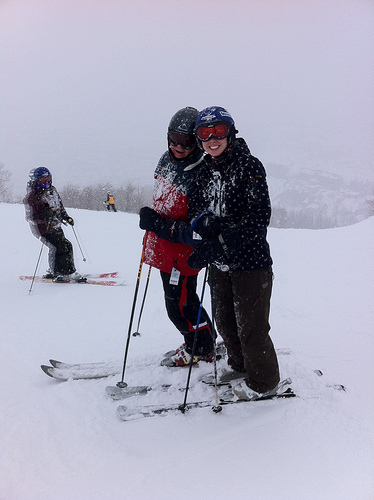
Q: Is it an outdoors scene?
A: Yes, it is outdoors.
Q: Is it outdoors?
A: Yes, it is outdoors.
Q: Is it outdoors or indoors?
A: It is outdoors.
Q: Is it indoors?
A: No, it is outdoors.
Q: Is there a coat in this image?
A: Yes, there is a coat.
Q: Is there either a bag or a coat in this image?
A: Yes, there is a coat.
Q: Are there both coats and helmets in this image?
A: Yes, there are both a coat and a helmet.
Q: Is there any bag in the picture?
A: No, there are no bags.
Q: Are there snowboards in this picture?
A: No, there are no snowboards.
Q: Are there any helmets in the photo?
A: Yes, there is a helmet.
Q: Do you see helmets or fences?
A: Yes, there is a helmet.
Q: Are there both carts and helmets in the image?
A: No, there is a helmet but no carts.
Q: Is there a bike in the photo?
A: No, there are no bikes.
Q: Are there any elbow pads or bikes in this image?
A: No, there are no bikes or elbow pads.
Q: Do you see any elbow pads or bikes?
A: No, there are no bikes or elbow pads.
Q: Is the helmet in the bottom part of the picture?
A: No, the helmet is in the top of the image.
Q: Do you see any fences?
A: No, there are no fences.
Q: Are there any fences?
A: No, there are no fences.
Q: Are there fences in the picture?
A: No, there are no fences.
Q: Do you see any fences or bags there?
A: No, there are no fences or bags.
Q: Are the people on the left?
A: Yes, the people are on the left of the image.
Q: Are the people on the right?
A: No, the people are on the left of the image.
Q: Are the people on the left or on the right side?
A: The people are on the left of the image.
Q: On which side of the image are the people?
A: The people are on the left of the image.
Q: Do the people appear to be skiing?
A: Yes, the people are skiing.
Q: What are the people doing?
A: The people are skiing.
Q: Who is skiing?
A: The people are skiing.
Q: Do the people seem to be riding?
A: No, the people are skiing.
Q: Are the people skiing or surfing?
A: The people are skiing.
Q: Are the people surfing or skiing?
A: The people are skiing.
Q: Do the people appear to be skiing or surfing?
A: The people are skiing.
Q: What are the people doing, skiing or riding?
A: The people are skiing.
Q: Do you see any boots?
A: Yes, there are boots.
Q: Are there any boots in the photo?
A: Yes, there are boots.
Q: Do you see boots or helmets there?
A: Yes, there are boots.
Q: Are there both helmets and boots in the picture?
A: Yes, there are both boots and a helmet.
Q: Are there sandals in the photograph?
A: No, there are no sandals.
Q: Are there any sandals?
A: No, there are no sandals.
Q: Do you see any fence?
A: No, there are no fences.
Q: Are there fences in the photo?
A: No, there are no fences.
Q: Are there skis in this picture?
A: Yes, there are skis.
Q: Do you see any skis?
A: Yes, there are skis.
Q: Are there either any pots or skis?
A: Yes, there are skis.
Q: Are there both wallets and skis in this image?
A: No, there are skis but no wallets.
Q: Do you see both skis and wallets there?
A: No, there are skis but no wallets.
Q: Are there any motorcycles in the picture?
A: No, there are no motorcycles.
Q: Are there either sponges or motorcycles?
A: No, there are no motorcycles or sponges.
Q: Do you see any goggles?
A: Yes, there are goggles.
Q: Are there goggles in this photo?
A: Yes, there are goggles.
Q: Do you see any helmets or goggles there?
A: Yes, there are goggles.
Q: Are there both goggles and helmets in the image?
A: Yes, there are both goggles and a helmet.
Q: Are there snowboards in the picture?
A: No, there are no snowboards.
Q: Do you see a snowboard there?
A: No, there are no snowboards.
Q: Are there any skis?
A: Yes, there are skis.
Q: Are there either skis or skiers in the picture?
A: Yes, there are skis.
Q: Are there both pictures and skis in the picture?
A: No, there are skis but no pictures.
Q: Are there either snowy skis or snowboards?
A: Yes, there are snowy skis.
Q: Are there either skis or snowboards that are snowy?
A: Yes, the skis are snowy.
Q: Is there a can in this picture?
A: No, there are no cans.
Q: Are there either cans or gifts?
A: No, there are no cans or gifts.